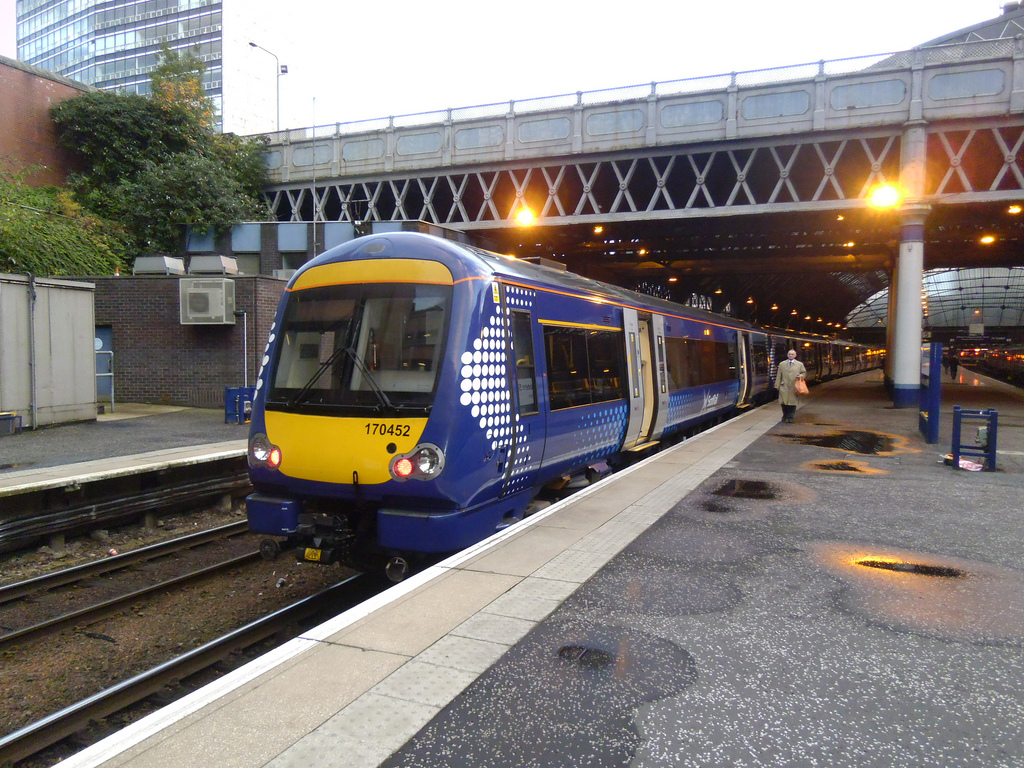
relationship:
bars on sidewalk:
[915, 407, 993, 470] [874, 504, 987, 716]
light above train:
[487, 184, 571, 236] [226, 206, 659, 544]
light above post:
[842, 156, 916, 217] [887, 230, 924, 395]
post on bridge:
[887, 230, 924, 395] [293, 44, 991, 228]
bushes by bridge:
[25, 89, 244, 249] [326, 39, 992, 206]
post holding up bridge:
[889, 113, 926, 407] [293, 44, 991, 228]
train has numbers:
[244, 215, 845, 546] [365, 420, 415, 442]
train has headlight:
[257, 273, 647, 537] [380, 432, 438, 495]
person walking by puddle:
[762, 346, 814, 422] [816, 426, 896, 483]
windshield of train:
[287, 314, 419, 384] [274, 232, 668, 501]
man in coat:
[771, 340, 810, 410] [779, 364, 792, 393]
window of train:
[517, 314, 632, 421] [238, 202, 774, 645]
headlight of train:
[379, 433, 438, 496] [197, 221, 785, 600]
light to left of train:
[487, 184, 594, 288] [244, 215, 845, 546]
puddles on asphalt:
[716, 409, 956, 654] [534, 377, 992, 753]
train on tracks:
[244, 215, 845, 546] [29, 517, 345, 675]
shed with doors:
[9, 210, 141, 472] [11, 273, 128, 442]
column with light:
[880, 189, 948, 427] [865, 169, 956, 249]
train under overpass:
[244, 215, 845, 546] [173, 22, 990, 319]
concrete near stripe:
[115, 366, 984, 751] [178, 372, 770, 755]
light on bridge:
[841, 156, 934, 214] [161, 7, 991, 280]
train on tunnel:
[225, 216, 872, 569] [531, 164, 903, 406]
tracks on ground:
[17, 503, 292, 730] [17, 496, 307, 764]